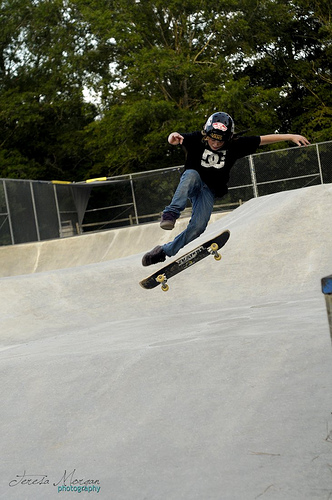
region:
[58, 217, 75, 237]
Grey trash can in the distance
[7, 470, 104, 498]
Teresa Morgan Photography copyright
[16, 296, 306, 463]
Grey concrete boarding area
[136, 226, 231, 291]
Black skateboard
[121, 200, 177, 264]
Black tennis shoes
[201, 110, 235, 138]
Black safety helmet with red logo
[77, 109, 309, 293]
Young boy performing board tricks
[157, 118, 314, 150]
Arms extended providing balance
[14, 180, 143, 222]
Chain link fence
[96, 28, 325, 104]
Green trees in background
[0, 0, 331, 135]
The sky is clear.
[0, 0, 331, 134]
The sky is white.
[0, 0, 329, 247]
Trees are in the background.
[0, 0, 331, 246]
The trees have leaves.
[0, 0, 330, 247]
The trees are green.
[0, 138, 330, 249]
A fence is in the background.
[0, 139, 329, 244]
The fence is gray.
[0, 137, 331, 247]
The fence is made of metal.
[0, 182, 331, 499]
The ground is gray.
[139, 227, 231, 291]
The skateboard is black.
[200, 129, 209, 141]
the boy's hair is blonde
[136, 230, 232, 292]
the skate board is black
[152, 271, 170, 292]
the back wheels on the skate board are yellow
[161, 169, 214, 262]
the boy's pants are blue jeans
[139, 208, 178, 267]
the boy's shoes are brown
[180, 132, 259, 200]
the boy's tee-shirt is black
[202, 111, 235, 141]
the boy's helmet is black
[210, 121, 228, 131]
there is a red oval on the boy's helmet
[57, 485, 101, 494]
the word photography is turquoise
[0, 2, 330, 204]
the trees in the background are large and leafy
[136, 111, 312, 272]
the man is skating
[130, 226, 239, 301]
this is a skate board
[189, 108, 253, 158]
the man has a helmet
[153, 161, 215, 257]
the man is in blue jeans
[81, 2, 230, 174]
this is a tree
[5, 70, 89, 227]
this is a tree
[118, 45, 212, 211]
this is a tree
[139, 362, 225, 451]
the ground is white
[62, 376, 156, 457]
the ground is white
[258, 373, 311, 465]
the ground is white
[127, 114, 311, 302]
booy and his skateboard in the air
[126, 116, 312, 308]
boy doing a skateboard trick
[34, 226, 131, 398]
grey concrete skateboard park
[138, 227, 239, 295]
black skateboard with yellow wheels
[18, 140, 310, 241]
silver chain link fence surrounding skateboard park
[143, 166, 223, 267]
boy wearing blue jeans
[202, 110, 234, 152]
black helmet with a white sticker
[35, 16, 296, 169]
tall green trees in the background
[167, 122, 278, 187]
boy wearing a black t-shirt with white design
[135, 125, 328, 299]
boy with arms out to side for balance